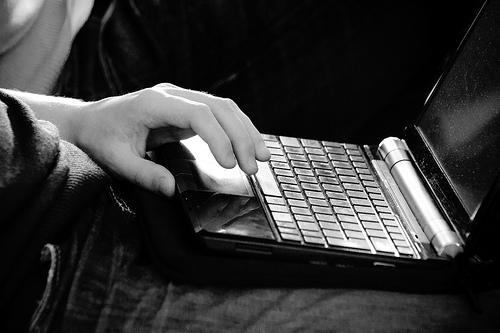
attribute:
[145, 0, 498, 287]
laptop — black, plastic, part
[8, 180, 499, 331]
pants — black, denim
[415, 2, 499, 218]
screen — dusty, off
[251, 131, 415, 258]
keyboard — shiny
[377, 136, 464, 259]
hinge — gray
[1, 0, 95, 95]
cloth — white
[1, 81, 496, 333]
man — sitting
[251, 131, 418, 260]
keys — part, silver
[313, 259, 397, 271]
ports — auxillery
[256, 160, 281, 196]
space bar — part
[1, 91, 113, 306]
sweater — part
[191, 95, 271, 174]
fingers — part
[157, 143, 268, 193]
nails — trimmed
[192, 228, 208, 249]
corner — round